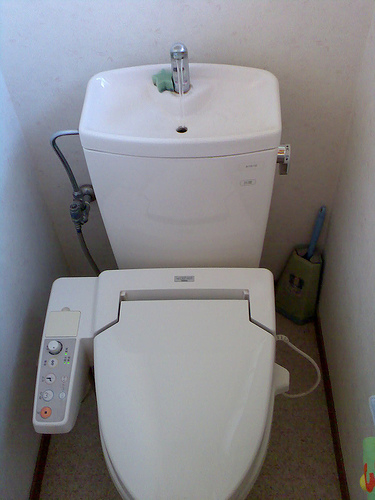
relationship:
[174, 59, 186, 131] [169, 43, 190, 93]
water on faucet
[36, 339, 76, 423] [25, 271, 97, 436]
button panel on armrest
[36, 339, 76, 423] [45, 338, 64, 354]
button panel has button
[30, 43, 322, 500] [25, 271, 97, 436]
toilet has armrest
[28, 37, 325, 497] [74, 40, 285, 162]
toilet has lid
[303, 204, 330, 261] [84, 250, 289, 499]
brush to clean toilet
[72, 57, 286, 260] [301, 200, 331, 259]
toilet bowl next handle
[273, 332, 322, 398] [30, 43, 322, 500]
wire side toilet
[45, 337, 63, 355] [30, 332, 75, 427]
white knob on button panel